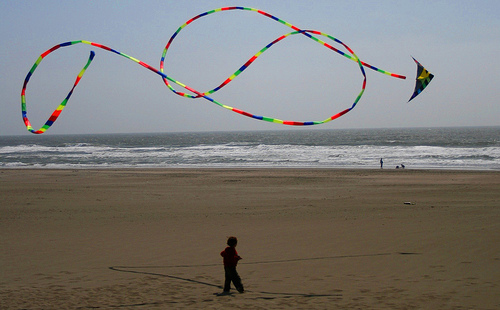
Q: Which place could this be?
A: It is a beach.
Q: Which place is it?
A: It is a beach.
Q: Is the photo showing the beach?
A: Yes, it is showing the beach.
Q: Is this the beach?
A: Yes, it is the beach.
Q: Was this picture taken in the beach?
A: Yes, it was taken in the beach.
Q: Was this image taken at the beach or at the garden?
A: It was taken at the beach.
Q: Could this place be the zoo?
A: No, it is the beach.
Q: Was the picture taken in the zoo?
A: No, the picture was taken in the beach.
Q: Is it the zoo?
A: No, it is the beach.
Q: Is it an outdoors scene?
A: Yes, it is outdoors.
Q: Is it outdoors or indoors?
A: It is outdoors.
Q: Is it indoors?
A: No, it is outdoors.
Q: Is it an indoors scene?
A: No, it is outdoors.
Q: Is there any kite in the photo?
A: Yes, there is a kite.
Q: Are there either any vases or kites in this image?
A: Yes, there is a kite.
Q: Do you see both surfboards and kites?
A: No, there is a kite but no surfboards.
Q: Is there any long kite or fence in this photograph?
A: Yes, there is a long kite.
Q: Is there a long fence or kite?
A: Yes, there is a long kite.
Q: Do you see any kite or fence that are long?
A: Yes, the kite is long.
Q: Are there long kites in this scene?
A: Yes, there is a long kite.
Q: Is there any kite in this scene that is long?
A: Yes, there is a kite that is long.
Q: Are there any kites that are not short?
A: Yes, there is a long kite.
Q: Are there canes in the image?
A: No, there are no canes.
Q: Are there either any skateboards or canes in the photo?
A: No, there are no canes or skateboards.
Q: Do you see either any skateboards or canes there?
A: No, there are no canes or skateboards.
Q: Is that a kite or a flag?
A: That is a kite.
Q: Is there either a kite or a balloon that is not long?
A: No, there is a kite but it is long.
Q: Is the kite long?
A: Yes, the kite is long.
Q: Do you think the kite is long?
A: Yes, the kite is long.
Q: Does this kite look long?
A: Yes, the kite is long.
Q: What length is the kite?
A: The kite is long.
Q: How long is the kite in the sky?
A: The kite is long.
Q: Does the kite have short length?
A: No, the kite is long.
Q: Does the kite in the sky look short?
A: No, the kite is long.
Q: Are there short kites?
A: No, there is a kite but it is long.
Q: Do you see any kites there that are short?
A: No, there is a kite but it is long.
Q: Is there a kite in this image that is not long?
A: No, there is a kite but it is long.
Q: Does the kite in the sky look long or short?
A: The kite is long.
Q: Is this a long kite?
A: Yes, this is a long kite.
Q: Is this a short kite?
A: No, this is a long kite.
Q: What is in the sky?
A: The kite is in the sky.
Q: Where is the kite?
A: The kite is in the sky.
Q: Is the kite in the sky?
A: Yes, the kite is in the sky.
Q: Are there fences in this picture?
A: No, there are no fences.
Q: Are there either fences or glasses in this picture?
A: No, there are no fences or glasses.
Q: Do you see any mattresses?
A: No, there are no mattresses.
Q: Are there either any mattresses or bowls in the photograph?
A: No, there are no mattresses or bowls.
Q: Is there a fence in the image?
A: No, there are no fences.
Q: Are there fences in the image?
A: No, there are no fences.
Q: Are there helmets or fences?
A: No, there are no fences or helmets.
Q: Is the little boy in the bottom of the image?
A: Yes, the boy is in the bottom of the image.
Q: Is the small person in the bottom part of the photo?
A: Yes, the boy is in the bottom of the image.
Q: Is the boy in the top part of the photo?
A: No, the boy is in the bottom of the image.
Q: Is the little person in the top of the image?
A: No, the boy is in the bottom of the image.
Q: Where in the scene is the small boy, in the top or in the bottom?
A: The boy is in the bottom of the image.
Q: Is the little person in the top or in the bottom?
A: The boy is in the bottom of the image.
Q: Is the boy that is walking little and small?
A: Yes, the boy is little and small.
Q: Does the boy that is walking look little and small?
A: Yes, the boy is little and small.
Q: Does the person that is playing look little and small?
A: Yes, the boy is little and small.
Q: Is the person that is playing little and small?
A: Yes, the boy is little and small.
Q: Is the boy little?
A: Yes, the boy is little.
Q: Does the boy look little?
A: Yes, the boy is little.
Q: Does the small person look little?
A: Yes, the boy is little.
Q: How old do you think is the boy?
A: The boy is little.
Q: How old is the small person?
A: The boy is little.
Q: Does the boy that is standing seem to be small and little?
A: Yes, the boy is small and little.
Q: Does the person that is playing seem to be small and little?
A: Yes, the boy is small and little.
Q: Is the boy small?
A: Yes, the boy is small.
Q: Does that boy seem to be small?
A: Yes, the boy is small.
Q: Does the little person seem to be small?
A: Yes, the boy is small.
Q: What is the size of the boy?
A: The boy is small.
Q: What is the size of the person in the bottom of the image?
A: The boy is small.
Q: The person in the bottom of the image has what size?
A: The boy is small.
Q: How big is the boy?
A: The boy is small.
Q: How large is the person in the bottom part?
A: The boy is small.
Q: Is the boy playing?
A: Yes, the boy is playing.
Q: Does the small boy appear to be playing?
A: Yes, the boy is playing.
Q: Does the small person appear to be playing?
A: Yes, the boy is playing.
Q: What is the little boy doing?
A: The boy is playing.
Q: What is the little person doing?
A: The boy is playing.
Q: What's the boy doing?
A: The boy is playing.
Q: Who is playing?
A: The boy is playing.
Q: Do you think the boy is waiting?
A: No, the boy is playing.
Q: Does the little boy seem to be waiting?
A: No, the boy is playing.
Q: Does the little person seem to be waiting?
A: No, the boy is playing.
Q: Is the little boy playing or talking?
A: The boy is playing.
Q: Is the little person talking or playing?
A: The boy is playing.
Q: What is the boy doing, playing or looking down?
A: The boy is playing.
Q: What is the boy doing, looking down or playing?
A: The boy is playing.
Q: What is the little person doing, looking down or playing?
A: The boy is playing.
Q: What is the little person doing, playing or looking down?
A: The boy is playing.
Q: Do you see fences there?
A: No, there are no fences.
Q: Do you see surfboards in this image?
A: No, there are no surfboards.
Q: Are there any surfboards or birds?
A: No, there are no surfboards or birds.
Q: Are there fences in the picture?
A: No, there are no fences.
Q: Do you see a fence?
A: No, there are no fences.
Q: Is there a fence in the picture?
A: No, there are no fences.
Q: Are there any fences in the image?
A: No, there are no fences.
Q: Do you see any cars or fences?
A: No, there are no fences or cars.